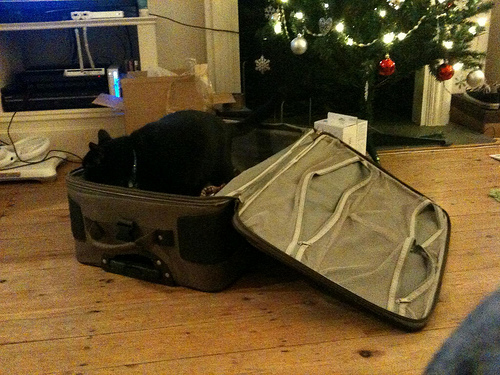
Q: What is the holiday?
A: Christmas.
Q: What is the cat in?
A: A suitcase.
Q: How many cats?
A: One.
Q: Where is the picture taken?
A: Close to tree.